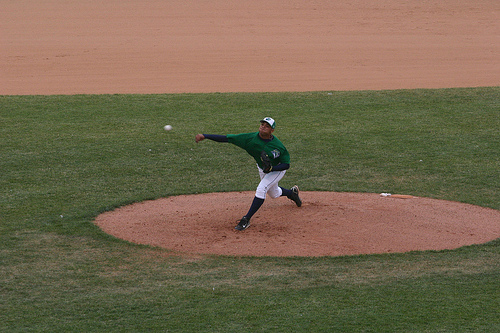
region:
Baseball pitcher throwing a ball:
[206, 112, 303, 222]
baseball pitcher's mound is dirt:
[131, 161, 471, 278]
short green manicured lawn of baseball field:
[31, 114, 131, 204]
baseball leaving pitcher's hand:
[154, 113, 180, 141]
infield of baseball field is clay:
[19, 16, 372, 71]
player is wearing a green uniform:
[227, 128, 292, 166]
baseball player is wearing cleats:
[292, 181, 306, 213]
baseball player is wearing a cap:
[260, 111, 278, 133]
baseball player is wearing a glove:
[258, 146, 280, 170]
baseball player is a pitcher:
[193, 106, 304, 227]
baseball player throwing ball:
[135, 81, 335, 271]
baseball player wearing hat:
[254, 108, 279, 138]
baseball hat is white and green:
[260, 113, 276, 131]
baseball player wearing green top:
[219, 125, 304, 173]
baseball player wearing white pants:
[247, 163, 292, 203]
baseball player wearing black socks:
[242, 188, 269, 230]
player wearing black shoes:
[231, 215, 248, 232]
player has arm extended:
[178, 115, 260, 160]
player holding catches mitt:
[252, 149, 292, 177]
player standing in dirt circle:
[80, 110, 496, 294]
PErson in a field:
[190, 95, 315, 247]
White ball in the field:
[152, 110, 169, 140]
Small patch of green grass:
[28, 275, 92, 325]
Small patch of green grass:
[88, 267, 147, 330]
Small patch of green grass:
[158, 278, 214, 330]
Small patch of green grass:
[208, 280, 277, 329]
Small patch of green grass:
[267, 276, 312, 331]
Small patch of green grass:
[320, 278, 371, 325]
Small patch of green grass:
[370, 278, 425, 324]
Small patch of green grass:
[425, 276, 484, 313]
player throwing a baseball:
[146, 96, 396, 263]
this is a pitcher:
[143, 82, 342, 227]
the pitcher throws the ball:
[110, 77, 387, 267]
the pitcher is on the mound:
[156, 90, 377, 266]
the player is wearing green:
[156, 85, 399, 281]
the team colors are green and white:
[142, 119, 381, 303]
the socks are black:
[222, 184, 294, 276]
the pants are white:
[231, 155, 348, 256]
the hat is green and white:
[234, 92, 303, 168]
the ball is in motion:
[116, 68, 361, 258]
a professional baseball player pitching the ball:
[126, 91, 320, 236]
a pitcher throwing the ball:
[150, 106, 318, 245]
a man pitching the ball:
[118, 92, 335, 247]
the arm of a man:
[191, 126, 247, 150]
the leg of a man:
[221, 187, 271, 227]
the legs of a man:
[223, 165, 320, 227]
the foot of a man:
[228, 212, 249, 234]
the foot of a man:
[288, 180, 311, 212]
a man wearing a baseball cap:
[253, 112, 277, 142]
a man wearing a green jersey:
[225, 111, 307, 170]